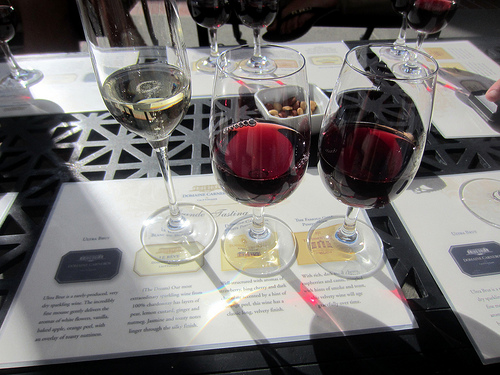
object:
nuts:
[262, 93, 319, 117]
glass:
[77, 1, 220, 264]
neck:
[150, 143, 180, 219]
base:
[220, 212, 298, 278]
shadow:
[184, 234, 500, 375]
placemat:
[0, 165, 421, 369]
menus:
[0, 38, 500, 141]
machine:
[467, 89, 500, 124]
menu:
[0, 173, 421, 375]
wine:
[211, 119, 426, 210]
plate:
[254, 84, 330, 133]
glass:
[305, 43, 440, 280]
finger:
[486, 80, 500, 102]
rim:
[141, 202, 384, 280]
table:
[0, 37, 500, 375]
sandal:
[261, 0, 323, 43]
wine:
[100, 62, 194, 142]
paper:
[0, 169, 419, 367]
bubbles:
[223, 118, 257, 134]